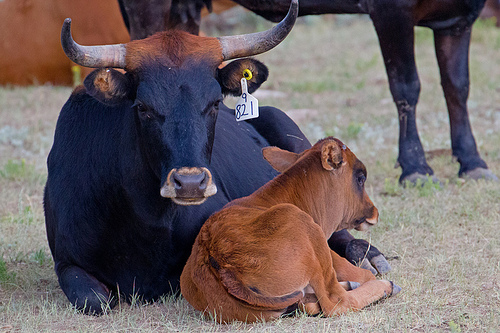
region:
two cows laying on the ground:
[33, 0, 421, 323]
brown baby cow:
[178, 124, 405, 320]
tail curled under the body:
[202, 258, 314, 318]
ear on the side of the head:
[317, 138, 344, 171]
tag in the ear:
[231, 72, 262, 127]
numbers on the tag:
[229, 85, 262, 124]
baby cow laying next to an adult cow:
[38, 2, 414, 317]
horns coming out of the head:
[47, 0, 312, 70]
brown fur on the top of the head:
[120, 29, 224, 68]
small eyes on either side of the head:
[129, 101, 224, 127]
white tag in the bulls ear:
[230, 83, 258, 118]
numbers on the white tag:
[231, 97, 256, 114]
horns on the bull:
[50, 0, 310, 65]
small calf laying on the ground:
[176, 135, 448, 325]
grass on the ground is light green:
[400, 216, 465, 306]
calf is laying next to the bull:
[130, 122, 395, 312]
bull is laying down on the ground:
[27, 5, 245, 315]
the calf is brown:
[164, 148, 415, 327]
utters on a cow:
[166, 2, 222, 22]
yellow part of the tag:
[238, 68, 253, 81]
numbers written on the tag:
[228, 88, 263, 125]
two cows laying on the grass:
[34, 0, 433, 328]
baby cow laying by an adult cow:
[31, 0, 413, 319]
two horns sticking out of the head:
[48, 0, 310, 82]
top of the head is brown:
[120, 28, 222, 73]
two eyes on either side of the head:
[136, 100, 231, 122]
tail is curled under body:
[210, 258, 322, 319]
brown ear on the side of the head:
[318, 134, 347, 174]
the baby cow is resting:
[196, 115, 398, 330]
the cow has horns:
[25, 8, 279, 226]